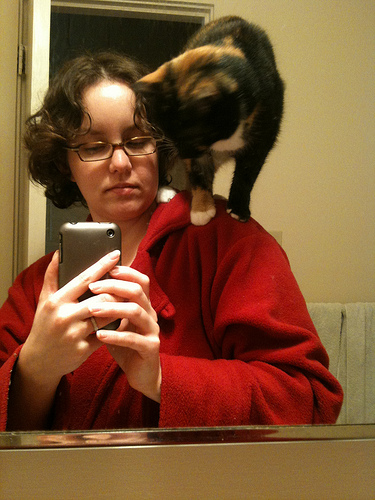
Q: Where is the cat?
A: On the shoulder.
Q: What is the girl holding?
A: A phone.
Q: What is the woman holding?
A: A phone.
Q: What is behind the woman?
A: The bathroom door.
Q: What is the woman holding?
A: A smartphone.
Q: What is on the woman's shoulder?
A: A cat.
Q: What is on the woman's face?
A: Glasses.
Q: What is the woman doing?
A: Taking a selfie.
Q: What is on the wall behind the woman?
A: A towel bar with towels.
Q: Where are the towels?
A: On the towel bar.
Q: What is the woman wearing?
A: A red robe.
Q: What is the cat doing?
A: Standing on the woman's shoulder.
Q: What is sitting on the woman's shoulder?
A: A cat.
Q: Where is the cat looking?
A: Cat looking down from woman's shoulder.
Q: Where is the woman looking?
A: At the phone.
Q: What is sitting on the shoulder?
A: Calico cat sitting on a woman's shoulder.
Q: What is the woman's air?
A: Brown.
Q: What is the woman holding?
A: The woman is holding a cell phone.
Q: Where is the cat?
A: On the woman's shoulder.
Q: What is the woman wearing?
A: A robe.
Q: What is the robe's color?
A: Red.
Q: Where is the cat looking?
A: At the cell phone.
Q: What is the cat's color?
A: Multicolored.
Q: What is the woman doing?
A: Taking a picture.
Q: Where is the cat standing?
A: On the woman's shoulder.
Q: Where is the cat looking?
A: Down at the woman's shoulder.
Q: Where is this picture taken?
A: In the bathroom.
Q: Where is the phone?
A: In the woman's hands.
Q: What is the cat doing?
A: Standing on the woman's shoulder.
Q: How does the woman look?
A: She looks sad.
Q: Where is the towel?
A: On the wall.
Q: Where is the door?
A: Behind the woman.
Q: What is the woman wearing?
A: A bath robe.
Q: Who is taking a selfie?
A: The woman.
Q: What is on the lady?
A: Cat.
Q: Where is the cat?
A: On the lady.